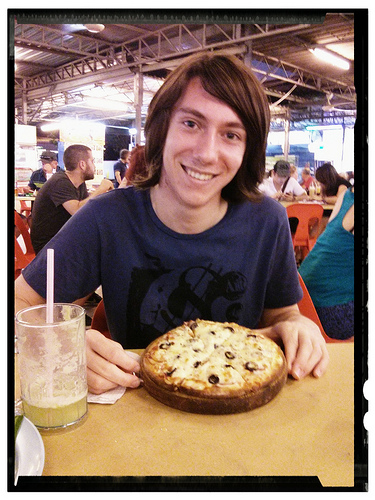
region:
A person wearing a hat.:
[259, 159, 311, 204]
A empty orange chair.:
[284, 201, 323, 261]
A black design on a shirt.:
[117, 264, 248, 347]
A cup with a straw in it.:
[14, 248, 89, 434]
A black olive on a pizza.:
[206, 370, 221, 385]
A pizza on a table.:
[137, 316, 289, 416]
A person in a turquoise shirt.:
[290, 182, 354, 342]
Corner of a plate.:
[14, 410, 47, 480]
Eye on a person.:
[179, 115, 204, 133]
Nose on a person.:
[188, 122, 219, 164]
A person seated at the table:
[84, 59, 293, 330]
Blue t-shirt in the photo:
[137, 243, 258, 306]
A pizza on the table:
[181, 332, 257, 391]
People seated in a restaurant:
[31, 131, 346, 269]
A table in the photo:
[165, 424, 282, 463]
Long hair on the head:
[143, 51, 269, 123]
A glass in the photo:
[46, 342, 80, 407]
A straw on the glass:
[40, 243, 66, 369]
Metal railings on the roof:
[60, 40, 165, 73]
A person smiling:
[170, 103, 232, 194]